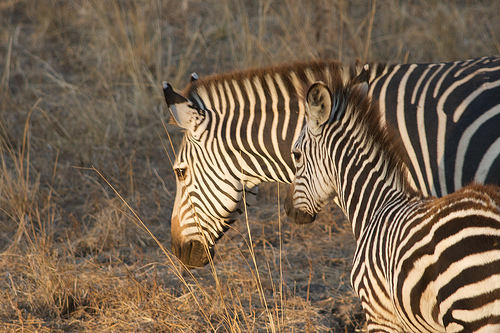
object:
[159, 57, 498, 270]
zebra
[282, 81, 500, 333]
zebras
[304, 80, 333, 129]
left ear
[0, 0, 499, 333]
grass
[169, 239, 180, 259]
nose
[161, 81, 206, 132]
ear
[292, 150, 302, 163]
eye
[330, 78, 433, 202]
mane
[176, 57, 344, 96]
mane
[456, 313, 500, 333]
strips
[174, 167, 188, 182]
eye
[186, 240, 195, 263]
mouth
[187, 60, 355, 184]
neck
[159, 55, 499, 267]
mother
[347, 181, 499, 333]
baby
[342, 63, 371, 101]
ear